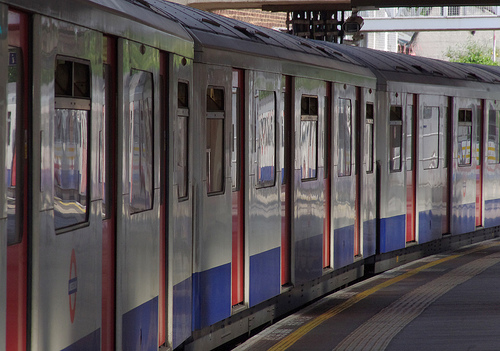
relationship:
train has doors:
[8, 3, 498, 346] [7, 10, 499, 350]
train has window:
[8, 3, 498, 346] [52, 48, 497, 235]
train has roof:
[8, 3, 498, 346] [54, 1, 499, 89]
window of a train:
[52, 48, 497, 235] [8, 3, 498, 346]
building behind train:
[222, 0, 288, 30] [8, 3, 498, 346]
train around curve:
[8, 3, 498, 346] [193, 265, 493, 345]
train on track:
[8, 3, 498, 346] [210, 256, 488, 348]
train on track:
[8, 3, 498, 346] [259, 247, 459, 348]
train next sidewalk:
[8, 3, 498, 346] [322, 262, 491, 347]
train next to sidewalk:
[8, 3, 498, 346] [228, 226, 498, 344]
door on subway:
[28, 23, 117, 350] [2, 3, 498, 350]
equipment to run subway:
[286, 6, 364, 44] [2, 3, 498, 350]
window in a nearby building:
[435, 4, 462, 14] [355, 6, 498, 22]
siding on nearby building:
[366, 30, 498, 64] [346, 17, 498, 64]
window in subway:
[332, 95, 364, 180] [2, 3, 498, 350]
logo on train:
[66, 250, 83, 326] [8, 3, 498, 346]